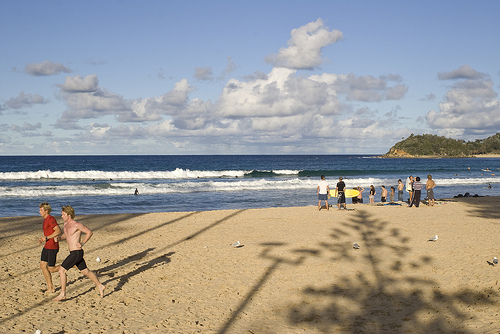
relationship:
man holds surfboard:
[333, 176, 347, 211] [326, 188, 361, 198]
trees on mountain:
[406, 129, 498, 154] [379, 131, 497, 160]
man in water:
[132, 187, 139, 197] [4, 151, 500, 212]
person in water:
[466, 165, 472, 173] [4, 151, 500, 212]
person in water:
[483, 167, 489, 173] [4, 151, 500, 212]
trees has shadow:
[247, 174, 484, 331] [299, 206, 464, 333]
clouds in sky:
[270, 17, 342, 74] [2, 3, 496, 159]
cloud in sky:
[27, 60, 73, 79] [2, 3, 496, 159]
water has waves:
[4, 151, 500, 212] [2, 169, 311, 178]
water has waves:
[4, 151, 500, 212] [2, 177, 494, 196]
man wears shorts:
[55, 204, 107, 302] [62, 248, 87, 270]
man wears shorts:
[33, 199, 66, 296] [62, 248, 87, 270]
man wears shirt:
[33, 199, 66, 296] [41, 214, 59, 249]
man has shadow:
[55, 204, 107, 302] [65, 249, 174, 296]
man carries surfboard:
[333, 176, 347, 211] [326, 188, 361, 198]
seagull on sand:
[429, 233, 439, 243] [2, 201, 500, 332]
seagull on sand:
[229, 239, 244, 249] [2, 201, 500, 332]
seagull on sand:
[489, 256, 497, 269] [2, 201, 500, 332]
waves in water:
[2, 169, 311, 178] [4, 151, 500, 212]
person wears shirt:
[314, 174, 331, 209] [318, 179, 329, 195]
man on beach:
[55, 204, 107, 302] [2, 200, 498, 332]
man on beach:
[33, 199, 66, 296] [2, 200, 498, 332]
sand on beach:
[2, 201, 500, 332] [2, 200, 498, 332]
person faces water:
[314, 174, 331, 209] [4, 151, 500, 212]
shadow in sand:
[299, 206, 464, 333] [2, 201, 500, 332]